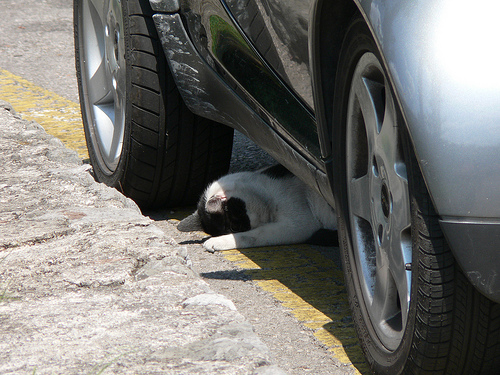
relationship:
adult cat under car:
[176, 164, 340, 251] [71, 4, 494, 373]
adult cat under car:
[176, 164, 340, 251] [175, 139, 370, 269]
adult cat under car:
[176, 164, 340, 251] [63, 1, 423, 371]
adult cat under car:
[176, 164, 340, 251] [107, 27, 421, 274]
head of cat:
[171, 157, 276, 246] [164, 157, 334, 254]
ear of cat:
[172, 210, 202, 239] [216, 164, 388, 294]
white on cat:
[274, 193, 308, 230] [170, 152, 345, 256]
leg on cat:
[193, 224, 313, 248] [155, 163, 309, 255]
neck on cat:
[229, 167, 285, 211] [174, 159, 303, 256]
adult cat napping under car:
[176, 164, 340, 251] [71, 4, 494, 373]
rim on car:
[342, 50, 414, 352] [71, 4, 494, 373]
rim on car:
[75, 0, 128, 179] [71, 4, 494, 373]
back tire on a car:
[66, 1, 241, 215] [71, 4, 494, 373]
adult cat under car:
[176, 164, 340, 251] [99, 4, 496, 269]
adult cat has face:
[176, 164, 340, 251] [206, 195, 276, 233]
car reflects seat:
[67, 3, 497, 323] [231, 5, 321, 132]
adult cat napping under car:
[176, 164, 340, 251] [70, 0, 499, 375]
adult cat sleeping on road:
[174, 167, 323, 272] [2, 2, 369, 371]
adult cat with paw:
[176, 164, 340, 251] [202, 231, 241, 260]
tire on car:
[323, 42, 428, 280] [71, 4, 494, 373]